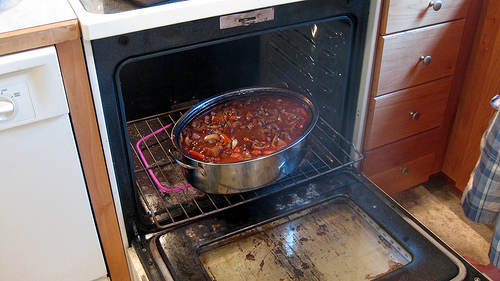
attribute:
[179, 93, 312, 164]
stew — red, cooking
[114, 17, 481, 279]
oven — dirty, black, open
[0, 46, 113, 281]
dishwasher — white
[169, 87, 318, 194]
pot — silver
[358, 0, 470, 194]
cabinet — wooden, brown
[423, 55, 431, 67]
knob — silver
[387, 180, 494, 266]
floor — biege, tan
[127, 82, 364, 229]
grate — out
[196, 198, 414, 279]
window — greasy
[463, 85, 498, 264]
shirt — plaid, blue, white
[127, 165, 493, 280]
oven door — dirty, open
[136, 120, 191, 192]
heated wire — pink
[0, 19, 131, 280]
frame — wooden